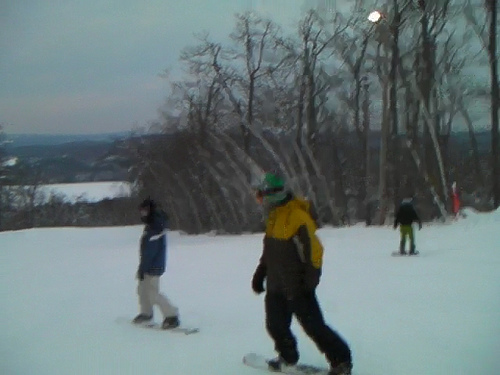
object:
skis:
[122, 317, 198, 336]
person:
[393, 199, 422, 253]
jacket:
[260, 203, 328, 293]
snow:
[3, 202, 495, 373]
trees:
[409, 0, 445, 225]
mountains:
[2, 118, 499, 175]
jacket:
[135, 214, 166, 275]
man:
[134, 195, 174, 327]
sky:
[6, 0, 495, 136]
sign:
[449, 184, 465, 215]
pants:
[400, 226, 420, 253]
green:
[402, 227, 416, 239]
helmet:
[256, 173, 291, 208]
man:
[259, 181, 343, 372]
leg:
[138, 275, 153, 319]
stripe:
[139, 232, 175, 242]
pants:
[260, 284, 354, 368]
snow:
[7, 169, 145, 202]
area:
[1, 175, 135, 211]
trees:
[310, 4, 374, 225]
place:
[3, 1, 496, 367]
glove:
[253, 266, 274, 295]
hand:
[251, 265, 269, 294]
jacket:
[392, 206, 421, 231]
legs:
[266, 285, 297, 366]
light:
[364, 11, 381, 20]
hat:
[395, 195, 418, 207]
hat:
[138, 198, 157, 218]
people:
[373, 186, 383, 225]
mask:
[140, 201, 154, 224]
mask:
[401, 197, 412, 203]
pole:
[372, 18, 398, 233]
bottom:
[256, 223, 330, 294]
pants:
[137, 268, 178, 325]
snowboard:
[236, 348, 375, 373]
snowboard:
[390, 250, 421, 257]